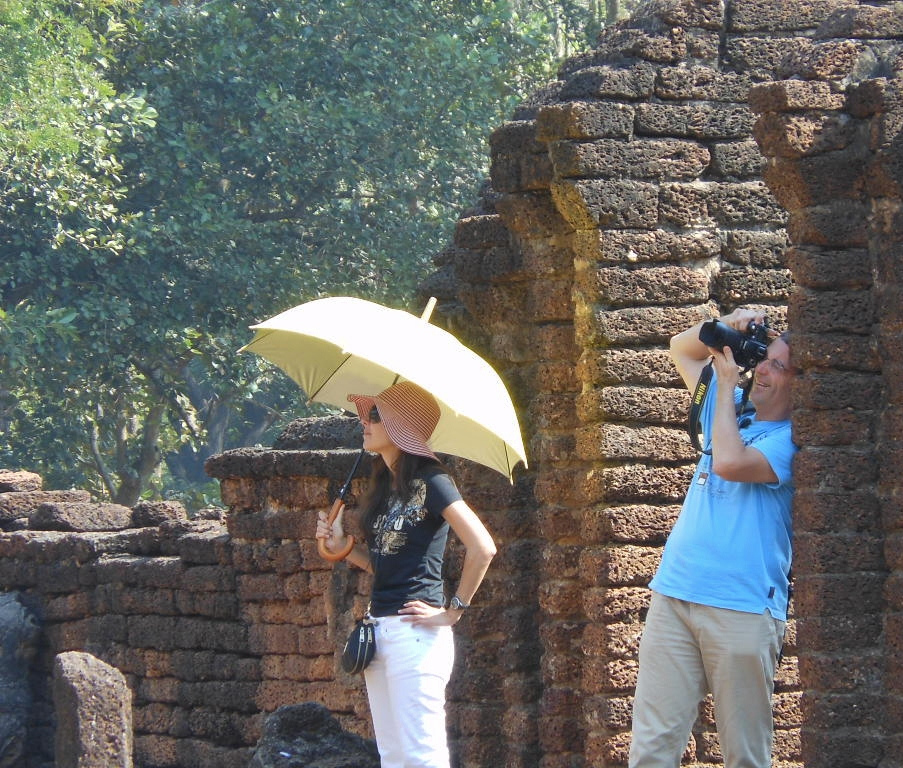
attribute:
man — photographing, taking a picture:
[629, 302, 792, 765]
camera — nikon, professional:
[697, 318, 767, 376]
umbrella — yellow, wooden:
[244, 292, 532, 488]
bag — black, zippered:
[339, 616, 376, 671]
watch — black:
[449, 592, 466, 613]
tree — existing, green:
[1, 0, 652, 500]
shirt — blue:
[651, 368, 794, 619]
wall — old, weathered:
[540, 3, 901, 766]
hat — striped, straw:
[350, 383, 438, 459]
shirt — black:
[362, 465, 460, 610]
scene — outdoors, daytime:
[2, 4, 900, 765]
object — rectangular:
[729, 643, 761, 662]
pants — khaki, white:
[630, 587, 786, 766]